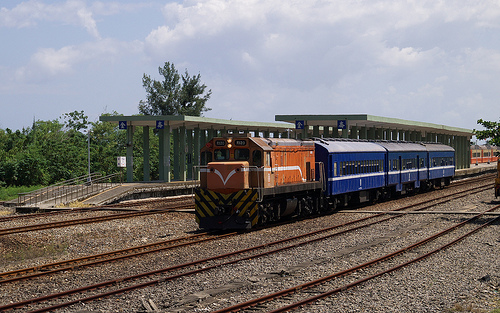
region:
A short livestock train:
[190, 124, 465, 233]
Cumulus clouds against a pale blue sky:
[12, 4, 223, 66]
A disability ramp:
[10, 165, 130, 217]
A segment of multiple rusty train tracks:
[18, 213, 307, 308]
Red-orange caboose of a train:
[190, 129, 328, 229]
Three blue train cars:
[321, 135, 463, 205]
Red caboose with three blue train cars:
[192, 125, 462, 232]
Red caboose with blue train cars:
[191, 133, 461, 226]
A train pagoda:
[97, 102, 194, 188]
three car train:
[184, 115, 463, 238]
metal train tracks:
[6, 239, 335, 309]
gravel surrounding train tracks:
[6, 243, 495, 311]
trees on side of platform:
[2, 53, 213, 200]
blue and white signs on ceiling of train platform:
[111, 115, 176, 132]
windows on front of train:
[210, 145, 252, 165]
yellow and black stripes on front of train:
[191, 186, 261, 228]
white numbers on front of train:
[210, 138, 252, 150]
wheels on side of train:
[261, 174, 456, 224]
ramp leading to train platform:
[2, 165, 129, 216]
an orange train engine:
[195, 130, 322, 236]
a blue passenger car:
[316, 139, 390, 208]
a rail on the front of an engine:
[247, 162, 267, 201]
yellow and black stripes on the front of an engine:
[190, 186, 267, 227]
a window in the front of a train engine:
[232, 146, 252, 161]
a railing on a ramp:
[54, 168, 125, 209]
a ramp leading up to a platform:
[18, 172, 131, 214]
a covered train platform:
[104, 110, 296, 186]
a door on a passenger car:
[396, 153, 404, 188]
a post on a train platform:
[158, 122, 171, 181]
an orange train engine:
[194, 129, 318, 240]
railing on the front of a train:
[245, 163, 265, 208]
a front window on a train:
[234, 145, 250, 162]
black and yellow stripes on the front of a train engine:
[191, 187, 264, 227]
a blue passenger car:
[315, 134, 389, 204]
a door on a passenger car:
[396, 154, 405, 186]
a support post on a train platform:
[158, 124, 170, 182]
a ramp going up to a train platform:
[80, 180, 140, 208]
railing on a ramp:
[47, 166, 127, 208]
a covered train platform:
[94, 111, 301, 183]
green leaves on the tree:
[161, 83, 174, 92]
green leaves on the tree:
[192, 71, 201, 91]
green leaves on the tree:
[90, 136, 110, 163]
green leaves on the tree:
[50, 139, 74, 168]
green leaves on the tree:
[65, 101, 85, 130]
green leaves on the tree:
[25, 153, 52, 185]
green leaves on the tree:
[8, 132, 26, 146]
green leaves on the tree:
[34, 115, 81, 158]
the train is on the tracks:
[194, 133, 459, 223]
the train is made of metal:
[193, 134, 455, 225]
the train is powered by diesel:
[197, 135, 317, 225]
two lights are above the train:
[227, 137, 232, 149]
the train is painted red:
[200, 133, 318, 219]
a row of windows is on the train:
[331, 157, 458, 177]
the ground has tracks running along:
[2, 175, 494, 310]